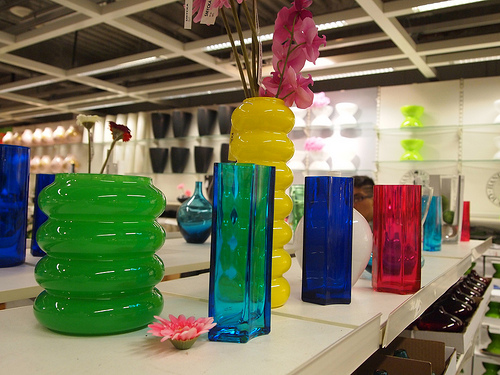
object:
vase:
[151, 112, 171, 139]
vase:
[172, 111, 193, 138]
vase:
[197, 108, 219, 137]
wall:
[112, 107, 253, 205]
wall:
[277, 89, 375, 194]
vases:
[287, 102, 361, 176]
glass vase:
[207, 162, 276, 344]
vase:
[29, 172, 166, 338]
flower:
[75, 113, 102, 174]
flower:
[101, 120, 133, 174]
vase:
[292, 207, 373, 288]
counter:
[0, 249, 473, 375]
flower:
[293, 17, 327, 66]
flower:
[147, 313, 218, 349]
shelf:
[285, 311, 385, 375]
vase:
[215, 96, 296, 309]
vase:
[370, 184, 422, 295]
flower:
[286, 64, 314, 109]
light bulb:
[417, 305, 463, 333]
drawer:
[397, 274, 494, 355]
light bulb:
[440, 293, 473, 318]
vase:
[420, 194, 442, 252]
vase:
[460, 200, 470, 242]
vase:
[176, 180, 212, 244]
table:
[0, 291, 382, 375]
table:
[420, 236, 493, 259]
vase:
[29, 173, 56, 257]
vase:
[0, 143, 31, 268]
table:
[155, 256, 474, 349]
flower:
[284, 0, 314, 26]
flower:
[262, 76, 281, 95]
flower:
[182, 0, 243, 26]